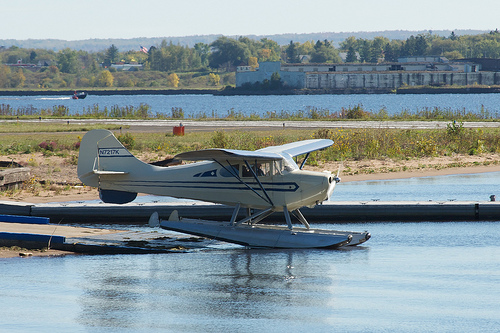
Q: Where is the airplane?
A: On the water.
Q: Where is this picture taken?
A: Outside by the water.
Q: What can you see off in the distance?
A: Trees.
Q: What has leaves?
A: The trees.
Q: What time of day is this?
A: It is daytime.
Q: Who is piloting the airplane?
A: A person.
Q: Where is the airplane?
A: On the water.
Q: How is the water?
A: Calm.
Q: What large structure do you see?
A: Building.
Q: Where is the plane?
A: Dock.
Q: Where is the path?
A: Between the two stretches of grass.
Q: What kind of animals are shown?
A: None.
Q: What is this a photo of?
A: An airplane.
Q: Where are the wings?
A: At the top of the plane.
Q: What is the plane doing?
A: Landing.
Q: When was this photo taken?
A: Daytime.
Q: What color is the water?
A: Blue.